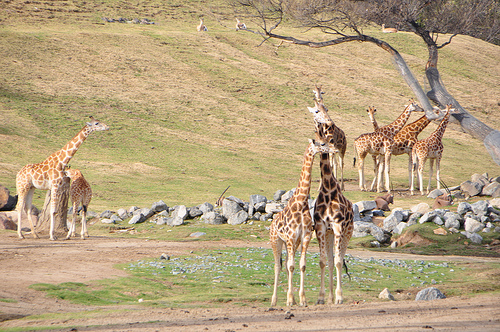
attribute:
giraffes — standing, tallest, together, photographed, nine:
[274, 122, 342, 301]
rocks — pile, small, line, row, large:
[119, 191, 473, 243]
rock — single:
[414, 282, 436, 304]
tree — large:
[384, 31, 499, 149]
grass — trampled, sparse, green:
[173, 244, 442, 300]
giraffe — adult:
[11, 112, 106, 252]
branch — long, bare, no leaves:
[375, 49, 436, 114]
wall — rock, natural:
[105, 196, 499, 226]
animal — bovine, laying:
[187, 18, 222, 35]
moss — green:
[366, 206, 497, 259]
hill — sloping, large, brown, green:
[8, 7, 456, 171]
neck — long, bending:
[56, 129, 89, 164]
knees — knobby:
[15, 208, 64, 219]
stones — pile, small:
[230, 184, 492, 213]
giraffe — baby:
[61, 162, 107, 230]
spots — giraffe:
[316, 192, 351, 221]